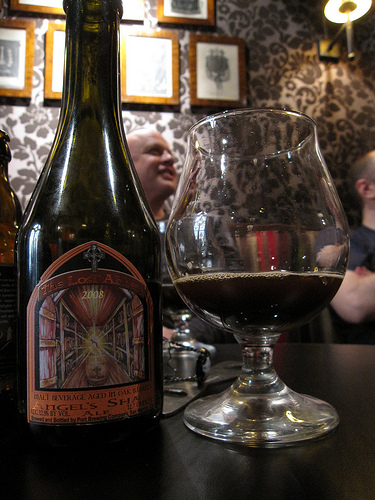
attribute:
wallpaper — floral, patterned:
[256, 16, 309, 95]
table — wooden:
[102, 440, 235, 487]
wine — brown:
[187, 273, 321, 322]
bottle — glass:
[12, 3, 165, 450]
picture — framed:
[192, 36, 245, 107]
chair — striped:
[252, 229, 315, 267]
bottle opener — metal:
[167, 346, 233, 394]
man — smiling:
[139, 133, 175, 223]